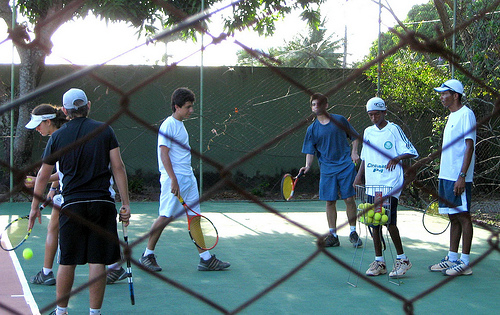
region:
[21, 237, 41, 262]
ball is green in color.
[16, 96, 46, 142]
Six people are seen.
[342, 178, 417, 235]
Basket of tennis ball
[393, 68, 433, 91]
Plants are green color.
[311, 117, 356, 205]
Boy in blue dress is holding the bat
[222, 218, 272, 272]
Ground is grey in color.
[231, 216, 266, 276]
Shadow is in ground.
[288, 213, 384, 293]
Fence is brown in color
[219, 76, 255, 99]
wall is white color.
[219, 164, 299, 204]
plants are in the sides of the wall.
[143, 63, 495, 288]
People getting ready to play tennis.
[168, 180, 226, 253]
Young man holding tennis racket.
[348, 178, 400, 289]
Wire container holding yellow tennis balls.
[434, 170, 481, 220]
Young man wearing blue and white shorts.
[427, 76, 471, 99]
Young man wearing white cap.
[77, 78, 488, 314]
Wire fence surrounding tennis court.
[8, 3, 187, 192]
Tree growing outside of fence next to tennis court.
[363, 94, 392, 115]
Young boy wearing white cap backwards.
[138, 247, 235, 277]
Young man wearing gray tennis shoes.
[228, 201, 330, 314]
A green tennis court.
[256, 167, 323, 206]
A TENNIS RACKET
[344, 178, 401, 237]
A CONTAINER OF TENNIS BALLS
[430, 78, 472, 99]
A WHITE HAT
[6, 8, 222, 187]
A TREE IN THE BACKGROUND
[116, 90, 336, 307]
A CHAIN LINK FENCE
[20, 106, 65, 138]
A WHITE SUN VISOR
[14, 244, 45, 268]
A GREEN TENNIS BALL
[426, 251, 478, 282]
A PAIR OF SNEAKERS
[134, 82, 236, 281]
A MAN WALKING WITH A TENNIS RACKET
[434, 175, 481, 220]
A PAIR OF BLUE AND WHITE SHORTS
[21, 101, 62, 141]
visor on a persons head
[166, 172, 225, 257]
tennis racket in a persons hand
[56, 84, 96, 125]
hat on a persons head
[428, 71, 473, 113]
glasses on top of a hat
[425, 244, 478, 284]
two white shoes with stripes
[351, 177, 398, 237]
tennis balls in a basket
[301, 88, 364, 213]
person with blue shorts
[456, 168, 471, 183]
watch on a wrist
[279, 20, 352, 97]
green tree behind a fence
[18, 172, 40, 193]
tennis ball in a hand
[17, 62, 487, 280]
6 people on the tennis court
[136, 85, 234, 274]
a man wearing all white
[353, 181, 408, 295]
a basket holding tennis balls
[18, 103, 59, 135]
a woman wearing a sun visor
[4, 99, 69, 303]
woman bouncing a ball on he court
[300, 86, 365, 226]
man wearing all blue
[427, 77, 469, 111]
white hat with sunglasses on them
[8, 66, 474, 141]
4 people wearing hats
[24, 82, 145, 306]
a man facing the other way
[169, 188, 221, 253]
red and black tennis racket